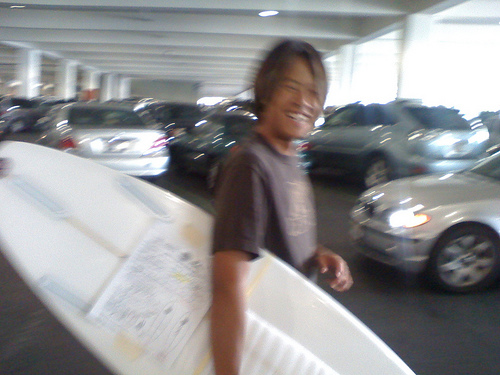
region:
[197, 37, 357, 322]
Blurry image of a surfer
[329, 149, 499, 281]
Car driving in a parking garage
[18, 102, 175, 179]
Car parked in a parking garage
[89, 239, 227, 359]
Paperwork attached to the surfboard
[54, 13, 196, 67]
Roof of a parking garage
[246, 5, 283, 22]
Overhead light in a parking garage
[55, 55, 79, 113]
Support column for a parking garage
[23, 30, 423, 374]
Surfer carrying his new surfboard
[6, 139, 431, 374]
Brand-new white surfboard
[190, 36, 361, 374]
Surfer walking through a parking garage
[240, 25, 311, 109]
smiling man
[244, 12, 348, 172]
smiling man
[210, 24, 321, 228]
smiling man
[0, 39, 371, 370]
a man walking with a surfboard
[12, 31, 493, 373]
a man holding a white surfboard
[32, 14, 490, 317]
a man walking with a white surfboard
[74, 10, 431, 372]
a man in a parking garage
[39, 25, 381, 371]
a man walking in a parking garage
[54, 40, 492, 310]
a man with long hair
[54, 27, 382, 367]
a man in a garage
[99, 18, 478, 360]
a man walking in a garage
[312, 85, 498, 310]
vehicles parked in the garage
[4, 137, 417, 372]
this is a surf board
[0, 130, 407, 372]
the surf board is white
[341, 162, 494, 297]
this is a car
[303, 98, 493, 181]
this is a car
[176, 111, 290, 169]
this is a car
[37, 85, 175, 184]
this is a car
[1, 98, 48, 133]
this is a car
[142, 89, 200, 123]
this is a car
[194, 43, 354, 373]
this is a man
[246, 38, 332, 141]
the smiling face of a man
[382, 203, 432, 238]
the headlight is on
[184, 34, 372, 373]
the man is smiling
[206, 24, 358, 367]
the man is holding a surfboard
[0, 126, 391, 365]
the surfboard is white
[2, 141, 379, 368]
the surfboard is long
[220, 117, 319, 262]
the shirt is brown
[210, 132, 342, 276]
the man is wearing a shirt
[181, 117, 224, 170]
the car is green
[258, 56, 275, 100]
his hair is long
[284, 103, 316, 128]
the man has teeth